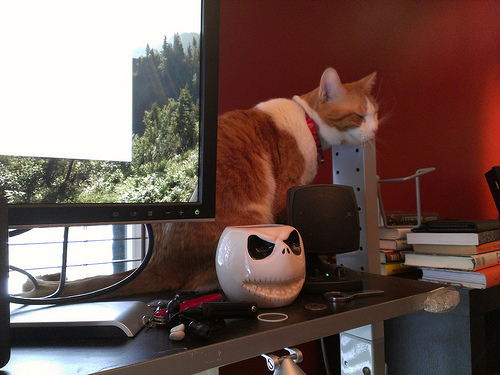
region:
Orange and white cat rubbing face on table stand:
[216, 61, 393, 199]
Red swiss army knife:
[148, 288, 221, 323]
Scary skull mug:
[215, 220, 309, 311]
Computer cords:
[21, 227, 156, 303]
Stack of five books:
[401, 221, 498, 294]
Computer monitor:
[3, 155, 218, 225]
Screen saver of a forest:
[134, 104, 201, 201]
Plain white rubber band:
[255, 305, 289, 325]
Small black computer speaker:
[285, 180, 372, 297]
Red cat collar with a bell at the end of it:
[298, 92, 337, 174]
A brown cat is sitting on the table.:
[245, 88, 406, 247]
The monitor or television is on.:
[143, 25, 247, 250]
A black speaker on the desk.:
[280, 161, 370, 298]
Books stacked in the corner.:
[402, 204, 493, 321]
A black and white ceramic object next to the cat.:
[204, 211, 312, 316]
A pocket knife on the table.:
[114, 288, 241, 346]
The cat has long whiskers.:
[328, 91, 398, 153]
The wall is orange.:
[263, 11, 479, 215]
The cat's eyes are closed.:
[325, 101, 383, 129]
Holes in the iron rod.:
[313, 146, 373, 276]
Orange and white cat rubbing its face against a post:
[18, 66, 386, 298]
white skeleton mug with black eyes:
[213, 220, 312, 308]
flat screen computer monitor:
[1, 0, 224, 230]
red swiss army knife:
[139, 288, 223, 331]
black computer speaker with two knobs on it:
[279, 180, 366, 297]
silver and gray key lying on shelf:
[322, 285, 392, 305]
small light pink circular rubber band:
[252, 311, 292, 323]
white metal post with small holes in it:
[323, 81, 392, 373]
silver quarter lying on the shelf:
[300, 300, 329, 312]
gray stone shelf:
[1, 263, 469, 373]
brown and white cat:
[24, 53, 395, 311]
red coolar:
[291, 96, 333, 166]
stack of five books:
[401, 216, 499, 302]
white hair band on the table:
[256, 306, 291, 326]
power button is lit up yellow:
[191, 206, 205, 218]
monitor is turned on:
[3, 1, 225, 236]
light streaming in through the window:
[8, 231, 145, 292]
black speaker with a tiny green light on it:
[280, 183, 372, 302]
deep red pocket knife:
[148, 290, 222, 328]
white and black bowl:
[206, 221, 307, 308]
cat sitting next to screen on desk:
[10, 57, 485, 304]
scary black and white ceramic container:
[210, 210, 320, 310]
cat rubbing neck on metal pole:
[291, 32, 396, 177]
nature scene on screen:
[5, 2, 210, 228]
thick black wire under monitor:
[10, 217, 160, 317]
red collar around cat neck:
[286, 80, 347, 175]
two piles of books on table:
[350, 196, 495, 296]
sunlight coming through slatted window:
[10, 210, 145, 292]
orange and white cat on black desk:
[25, 62, 395, 327]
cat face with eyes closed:
[318, 58, 406, 164]